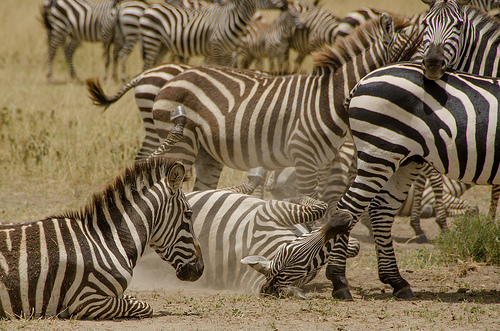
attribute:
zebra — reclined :
[2, 154, 206, 321]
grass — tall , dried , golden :
[21, 97, 125, 212]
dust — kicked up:
[158, 241, 253, 294]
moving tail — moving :
[70, 64, 128, 114]